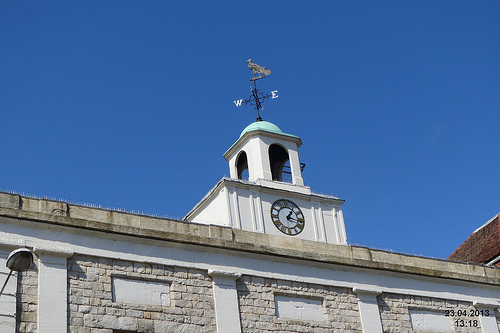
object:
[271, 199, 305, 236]
clock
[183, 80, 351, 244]
tower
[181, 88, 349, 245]
top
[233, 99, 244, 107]
w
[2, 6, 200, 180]
sky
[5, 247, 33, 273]
light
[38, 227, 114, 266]
shadow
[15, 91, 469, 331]
building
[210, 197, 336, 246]
white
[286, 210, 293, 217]
hands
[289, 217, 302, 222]
hands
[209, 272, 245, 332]
pillar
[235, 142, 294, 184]
window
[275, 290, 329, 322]
square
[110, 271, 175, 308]
square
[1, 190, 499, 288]
ledge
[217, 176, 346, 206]
ledge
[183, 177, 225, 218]
ledge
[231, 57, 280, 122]
vane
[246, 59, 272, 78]
bird